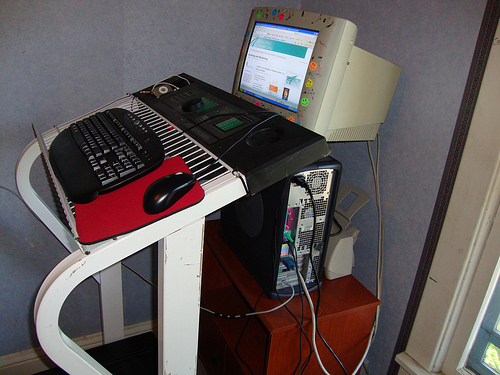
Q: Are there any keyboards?
A: Yes, there is a keyboard.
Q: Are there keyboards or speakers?
A: Yes, there is a keyboard.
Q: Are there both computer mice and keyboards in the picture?
A: Yes, there are both a keyboard and a computer mouse.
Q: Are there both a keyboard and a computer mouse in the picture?
A: Yes, there are both a keyboard and a computer mouse.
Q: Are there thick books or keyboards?
A: Yes, there is a thick keyboard.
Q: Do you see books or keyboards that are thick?
A: Yes, the keyboard is thick.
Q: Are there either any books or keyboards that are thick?
A: Yes, the keyboard is thick.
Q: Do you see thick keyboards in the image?
A: Yes, there is a thick keyboard.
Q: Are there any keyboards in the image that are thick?
A: Yes, there is a keyboard that is thick.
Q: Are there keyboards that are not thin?
A: Yes, there is a thick keyboard.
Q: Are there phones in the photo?
A: No, there are no phones.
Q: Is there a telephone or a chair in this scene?
A: No, there are no phones or chairs.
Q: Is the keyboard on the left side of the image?
A: Yes, the keyboard is on the left of the image.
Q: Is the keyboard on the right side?
A: No, the keyboard is on the left of the image.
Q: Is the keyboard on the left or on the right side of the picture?
A: The keyboard is on the left of the image.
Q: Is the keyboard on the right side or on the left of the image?
A: The keyboard is on the left of the image.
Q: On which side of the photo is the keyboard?
A: The keyboard is on the left of the image.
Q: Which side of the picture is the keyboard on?
A: The keyboard is on the left of the image.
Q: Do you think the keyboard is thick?
A: Yes, the keyboard is thick.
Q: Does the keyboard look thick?
A: Yes, the keyboard is thick.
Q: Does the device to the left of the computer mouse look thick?
A: Yes, the keyboard is thick.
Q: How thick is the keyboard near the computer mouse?
A: The keyboard is thick.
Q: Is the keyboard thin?
A: No, the keyboard is thick.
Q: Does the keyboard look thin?
A: No, the keyboard is thick.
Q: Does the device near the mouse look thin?
A: No, the keyboard is thick.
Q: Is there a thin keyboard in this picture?
A: No, there is a keyboard but it is thick.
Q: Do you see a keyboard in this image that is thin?
A: No, there is a keyboard but it is thick.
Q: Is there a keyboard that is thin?
A: No, there is a keyboard but it is thick.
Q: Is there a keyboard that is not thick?
A: No, there is a keyboard but it is thick.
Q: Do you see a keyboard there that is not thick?
A: No, there is a keyboard but it is thick.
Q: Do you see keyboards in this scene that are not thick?
A: No, there is a keyboard but it is thick.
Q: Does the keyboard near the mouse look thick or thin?
A: The keyboard is thick.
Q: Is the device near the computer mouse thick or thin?
A: The keyboard is thick.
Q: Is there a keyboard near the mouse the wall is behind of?
A: Yes, there is a keyboard near the mouse.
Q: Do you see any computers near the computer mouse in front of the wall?
A: No, there is a keyboard near the computer mouse.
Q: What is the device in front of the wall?
A: The device is a keyboard.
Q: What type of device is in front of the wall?
A: The device is a keyboard.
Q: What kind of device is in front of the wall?
A: The device is a keyboard.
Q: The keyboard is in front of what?
A: The keyboard is in front of the wall.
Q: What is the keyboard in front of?
A: The keyboard is in front of the wall.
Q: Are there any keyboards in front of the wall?
A: Yes, there is a keyboard in front of the wall.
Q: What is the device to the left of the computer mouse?
A: The device is a keyboard.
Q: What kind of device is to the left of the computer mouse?
A: The device is a keyboard.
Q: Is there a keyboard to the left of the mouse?
A: Yes, there is a keyboard to the left of the mouse.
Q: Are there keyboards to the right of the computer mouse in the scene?
A: No, the keyboard is to the left of the computer mouse.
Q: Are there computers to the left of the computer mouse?
A: No, there is a keyboard to the left of the computer mouse.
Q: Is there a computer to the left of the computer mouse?
A: No, there is a keyboard to the left of the computer mouse.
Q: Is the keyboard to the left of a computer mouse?
A: Yes, the keyboard is to the left of a computer mouse.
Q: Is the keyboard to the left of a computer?
A: No, the keyboard is to the left of a computer mouse.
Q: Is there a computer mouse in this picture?
A: Yes, there is a computer mouse.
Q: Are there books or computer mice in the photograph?
A: Yes, there is a computer mouse.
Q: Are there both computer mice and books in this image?
A: No, there is a computer mouse but no books.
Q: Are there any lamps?
A: No, there are no lamps.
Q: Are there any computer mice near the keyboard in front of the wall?
A: Yes, there is a computer mouse near the keyboard.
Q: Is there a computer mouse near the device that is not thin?
A: Yes, there is a computer mouse near the keyboard.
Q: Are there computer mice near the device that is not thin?
A: Yes, there is a computer mouse near the keyboard.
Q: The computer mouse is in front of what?
A: The computer mouse is in front of the wall.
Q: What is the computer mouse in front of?
A: The computer mouse is in front of the wall.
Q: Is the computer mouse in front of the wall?
A: Yes, the computer mouse is in front of the wall.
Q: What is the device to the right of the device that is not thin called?
A: The device is a computer mouse.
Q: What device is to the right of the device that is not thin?
A: The device is a computer mouse.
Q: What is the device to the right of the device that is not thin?
A: The device is a computer mouse.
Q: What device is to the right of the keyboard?
A: The device is a computer mouse.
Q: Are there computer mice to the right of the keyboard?
A: Yes, there is a computer mouse to the right of the keyboard.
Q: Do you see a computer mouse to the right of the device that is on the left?
A: Yes, there is a computer mouse to the right of the keyboard.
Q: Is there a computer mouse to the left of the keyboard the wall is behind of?
A: No, the computer mouse is to the right of the keyboard.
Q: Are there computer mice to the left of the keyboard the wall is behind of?
A: No, the computer mouse is to the right of the keyboard.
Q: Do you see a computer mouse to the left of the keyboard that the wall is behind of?
A: No, the computer mouse is to the right of the keyboard.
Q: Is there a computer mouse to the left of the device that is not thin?
A: No, the computer mouse is to the right of the keyboard.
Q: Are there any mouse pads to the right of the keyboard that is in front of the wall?
A: No, there is a computer mouse to the right of the keyboard.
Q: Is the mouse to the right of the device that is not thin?
A: Yes, the mouse is to the right of the keyboard.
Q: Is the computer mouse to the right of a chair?
A: No, the computer mouse is to the right of the keyboard.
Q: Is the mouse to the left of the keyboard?
A: No, the mouse is to the right of the keyboard.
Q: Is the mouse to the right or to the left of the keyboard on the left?
A: The mouse is to the right of the keyboard.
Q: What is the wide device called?
A: The device is a monitor.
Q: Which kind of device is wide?
A: The device is a monitor.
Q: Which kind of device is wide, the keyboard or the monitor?
A: The monitor is wide.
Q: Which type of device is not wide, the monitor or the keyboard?
A: The keyboard is not wide.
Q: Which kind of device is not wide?
A: The device is a keyboard.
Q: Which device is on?
A: The device is a monitor.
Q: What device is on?
A: The device is a monitor.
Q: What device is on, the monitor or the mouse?
A: The monitor is on.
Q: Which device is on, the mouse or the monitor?
A: The monitor is on.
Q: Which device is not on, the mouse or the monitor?
A: The mouse is not on.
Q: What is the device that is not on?
A: The device is a computer mouse.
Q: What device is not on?
A: The device is a computer mouse.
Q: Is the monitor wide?
A: Yes, the monitor is wide.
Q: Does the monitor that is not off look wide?
A: Yes, the monitor is wide.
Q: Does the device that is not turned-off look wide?
A: Yes, the monitor is wide.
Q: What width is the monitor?
A: The monitor is wide.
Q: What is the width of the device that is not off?
A: The monitor is wide.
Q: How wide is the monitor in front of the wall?
A: The monitor is wide.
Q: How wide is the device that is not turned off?
A: The monitor is wide.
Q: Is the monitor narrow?
A: No, the monitor is wide.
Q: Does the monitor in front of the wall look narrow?
A: No, the monitor is wide.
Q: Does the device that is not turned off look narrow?
A: No, the monitor is wide.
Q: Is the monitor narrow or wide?
A: The monitor is wide.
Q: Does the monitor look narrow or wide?
A: The monitor is wide.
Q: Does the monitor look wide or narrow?
A: The monitor is wide.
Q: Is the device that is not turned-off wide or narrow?
A: The monitor is wide.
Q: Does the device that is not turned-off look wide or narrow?
A: The monitor is wide.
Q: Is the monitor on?
A: Yes, the monitor is on.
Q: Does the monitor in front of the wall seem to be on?
A: Yes, the monitor is on.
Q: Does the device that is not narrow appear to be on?
A: Yes, the monitor is on.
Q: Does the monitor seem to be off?
A: No, the monitor is on.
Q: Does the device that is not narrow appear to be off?
A: No, the monitor is on.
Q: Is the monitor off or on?
A: The monitor is on.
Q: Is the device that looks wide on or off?
A: The monitor is on.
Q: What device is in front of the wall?
A: The device is a monitor.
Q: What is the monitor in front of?
A: The monitor is in front of the wall.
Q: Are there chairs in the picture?
A: No, there are no chairs.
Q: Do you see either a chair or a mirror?
A: No, there are no chairs or mirrors.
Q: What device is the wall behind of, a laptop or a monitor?
A: The wall is behind a monitor.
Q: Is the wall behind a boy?
A: No, the wall is behind a monitor.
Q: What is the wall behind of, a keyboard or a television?
A: The wall is behind a keyboard.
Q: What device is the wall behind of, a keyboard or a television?
A: The wall is behind a keyboard.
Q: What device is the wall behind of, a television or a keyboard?
A: The wall is behind a keyboard.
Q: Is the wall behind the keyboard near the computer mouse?
A: Yes, the wall is behind the keyboard.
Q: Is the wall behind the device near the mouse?
A: Yes, the wall is behind the keyboard.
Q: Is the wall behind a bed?
A: No, the wall is behind the keyboard.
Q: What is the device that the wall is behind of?
A: The device is a computer mouse.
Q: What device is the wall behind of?
A: The wall is behind the computer mouse.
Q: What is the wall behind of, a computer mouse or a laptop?
A: The wall is behind a computer mouse.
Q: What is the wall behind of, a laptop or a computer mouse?
A: The wall is behind a computer mouse.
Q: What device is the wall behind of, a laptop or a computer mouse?
A: The wall is behind a computer mouse.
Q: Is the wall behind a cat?
A: No, the wall is behind the computer mouse.